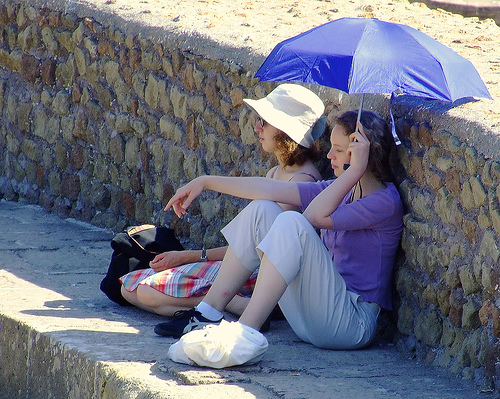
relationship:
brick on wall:
[163, 147, 190, 180] [2, 0, 476, 374]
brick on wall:
[453, 256, 474, 298] [2, 0, 476, 374]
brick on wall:
[407, 213, 435, 243] [2, 0, 476, 374]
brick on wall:
[163, 147, 186, 180] [2, 0, 476, 374]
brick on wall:
[404, 213, 431, 242] [2, 0, 476, 374]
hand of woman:
[156, 159, 261, 219] [216, 93, 400, 351]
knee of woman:
[269, 207, 313, 253] [249, 74, 414, 348]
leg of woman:
[235, 223, 303, 341] [272, 96, 422, 341]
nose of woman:
[249, 120, 268, 137] [150, 76, 310, 256]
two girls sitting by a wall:
[159, 57, 411, 349] [0, 0, 500, 396]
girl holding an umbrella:
[151, 112, 424, 366] [250, 3, 482, 143]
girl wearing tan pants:
[151, 112, 424, 366] [245, 197, 385, 360]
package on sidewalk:
[161, 319, 297, 369] [0, 197, 210, 385]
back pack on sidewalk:
[99, 218, 186, 299] [104, 319, 485, 397]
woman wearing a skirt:
[118, 82, 334, 333] [119, 258, 273, 299]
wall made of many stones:
[39, 25, 189, 188] [99, 57, 150, 107]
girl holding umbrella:
[151, 112, 424, 366] [262, 9, 491, 123]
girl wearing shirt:
[154, 112, 423, 366] [290, 170, 407, 306]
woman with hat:
[205, 66, 336, 243] [236, 69, 319, 145]